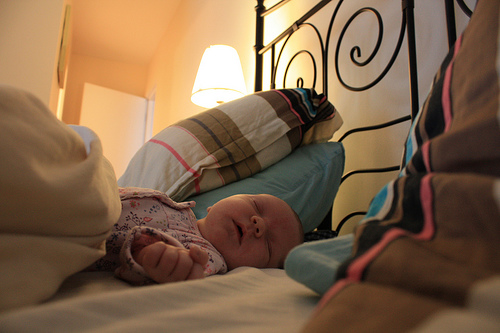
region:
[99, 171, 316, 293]
a baby sleeping on a bed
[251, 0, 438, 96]
the headboard of a bed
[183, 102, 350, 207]
two pillows on a ped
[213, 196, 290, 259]
a face of a baby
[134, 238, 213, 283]
a hand of a baby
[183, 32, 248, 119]
a lighted up lamp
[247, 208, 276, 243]
the nose of a baby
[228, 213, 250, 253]
the mouth of a baby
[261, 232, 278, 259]
the closed eye of a baby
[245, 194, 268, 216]
the closed eye of a baby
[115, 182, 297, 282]
the baby is asleep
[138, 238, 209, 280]
the baby's hand is closed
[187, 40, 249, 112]
the light is turned on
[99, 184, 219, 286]
the baby is wearing pajamas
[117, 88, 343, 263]
the pillows are behind the baby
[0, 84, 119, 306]
the blanket is on top of the baby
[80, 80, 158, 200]
the door is an open position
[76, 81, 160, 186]
the door is white in color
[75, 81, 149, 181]
the door is made of wood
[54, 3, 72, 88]
a picture is hanging on the wall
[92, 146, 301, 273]
sleeping baby in bed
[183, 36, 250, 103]
lamp is on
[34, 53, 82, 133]
doorway is open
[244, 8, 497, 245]
black scroll headboard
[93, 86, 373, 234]
pillows beside baby on bed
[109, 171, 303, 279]
baby's eyes are closed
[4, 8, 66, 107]
wall is cream colored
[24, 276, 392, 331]
white sheet on bed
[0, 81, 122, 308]
blanket on bed next to baby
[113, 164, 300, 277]
baby asleep next to pillow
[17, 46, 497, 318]
a baby sleeping in a bed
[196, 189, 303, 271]
the head of a baby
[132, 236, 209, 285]
the hand of a baby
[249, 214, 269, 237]
the nose of a baby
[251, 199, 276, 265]
the eyes of a baby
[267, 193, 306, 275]
the forehead of a baby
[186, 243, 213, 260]
the thumb of a baby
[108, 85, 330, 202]
a colorful pillow on a bed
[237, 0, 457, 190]
the headboard of a bed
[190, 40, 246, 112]
A lamp is turned on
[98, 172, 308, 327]
Baby is on a bed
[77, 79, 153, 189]
A white door is open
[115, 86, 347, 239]
Two pillows on the bed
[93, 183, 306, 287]
The baby is sleeping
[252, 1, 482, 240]
Black railings of the bed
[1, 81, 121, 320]
A blanket on the bed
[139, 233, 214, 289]
A hand of a baby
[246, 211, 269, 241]
Nose on baby's face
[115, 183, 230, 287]
Outfit the baby is wearing